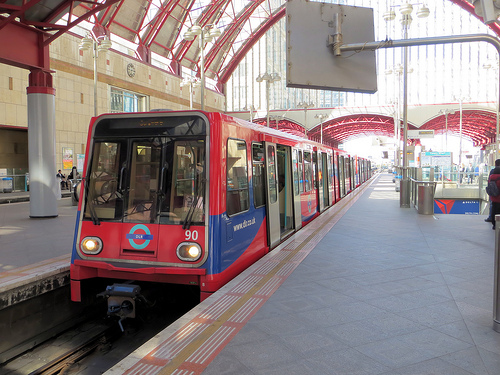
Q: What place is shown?
A: It is a train station.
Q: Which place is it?
A: It is a train station.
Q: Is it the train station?
A: Yes, it is the train station.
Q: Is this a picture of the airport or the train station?
A: It is showing the train station.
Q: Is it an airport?
A: No, it is a train station.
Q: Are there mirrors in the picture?
A: No, there are no mirrors.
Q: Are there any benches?
A: No, there are no benches.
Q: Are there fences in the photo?
A: No, there are no fences.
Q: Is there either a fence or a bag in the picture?
A: No, there are no fences or bags.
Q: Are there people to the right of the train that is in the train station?
A: Yes, there is a person to the right of the train.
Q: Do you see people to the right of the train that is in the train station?
A: Yes, there is a person to the right of the train.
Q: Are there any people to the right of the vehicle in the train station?
A: Yes, there is a person to the right of the train.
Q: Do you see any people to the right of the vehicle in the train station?
A: Yes, there is a person to the right of the train.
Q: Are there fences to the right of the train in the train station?
A: No, there is a person to the right of the train.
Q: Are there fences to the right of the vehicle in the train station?
A: No, there is a person to the right of the train.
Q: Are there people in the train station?
A: Yes, there is a person in the train station.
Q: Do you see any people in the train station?
A: Yes, there is a person in the train station.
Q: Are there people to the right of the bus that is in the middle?
A: Yes, there is a person to the right of the bus.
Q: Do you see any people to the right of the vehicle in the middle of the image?
A: Yes, there is a person to the right of the bus.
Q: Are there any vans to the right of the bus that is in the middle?
A: No, there is a person to the right of the bus.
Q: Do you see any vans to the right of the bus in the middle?
A: No, there is a person to the right of the bus.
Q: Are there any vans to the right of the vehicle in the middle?
A: No, there is a person to the right of the bus.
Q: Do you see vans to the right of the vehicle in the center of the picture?
A: No, there is a person to the right of the bus.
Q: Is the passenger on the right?
A: Yes, the passenger is on the right of the image.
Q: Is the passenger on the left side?
A: No, the passenger is on the right of the image.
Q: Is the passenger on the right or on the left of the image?
A: The passenger is on the right of the image.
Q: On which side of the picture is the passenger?
A: The passenger is on the right of the image.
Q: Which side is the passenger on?
A: The passenger is on the right of the image.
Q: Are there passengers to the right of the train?
A: Yes, there is a passenger to the right of the train.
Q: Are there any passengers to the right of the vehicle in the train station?
A: Yes, there is a passenger to the right of the train.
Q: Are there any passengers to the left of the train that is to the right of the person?
A: No, the passenger is to the right of the train.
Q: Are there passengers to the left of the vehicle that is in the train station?
A: No, the passenger is to the right of the train.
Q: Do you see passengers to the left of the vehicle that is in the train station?
A: No, the passenger is to the right of the train.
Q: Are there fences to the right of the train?
A: No, there is a passenger to the right of the train.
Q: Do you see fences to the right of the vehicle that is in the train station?
A: No, there is a passenger to the right of the train.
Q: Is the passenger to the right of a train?
A: Yes, the passenger is to the right of a train.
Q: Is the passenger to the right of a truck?
A: No, the passenger is to the right of a train.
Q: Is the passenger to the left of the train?
A: No, the passenger is to the right of the train.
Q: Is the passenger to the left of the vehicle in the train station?
A: No, the passenger is to the right of the train.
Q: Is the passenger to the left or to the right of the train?
A: The passenger is to the right of the train.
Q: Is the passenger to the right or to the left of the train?
A: The passenger is to the right of the train.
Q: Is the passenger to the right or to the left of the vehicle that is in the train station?
A: The passenger is to the right of the train.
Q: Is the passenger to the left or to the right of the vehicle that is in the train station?
A: The passenger is to the right of the train.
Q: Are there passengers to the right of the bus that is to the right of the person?
A: Yes, there is a passenger to the right of the bus.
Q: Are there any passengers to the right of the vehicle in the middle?
A: Yes, there is a passenger to the right of the bus.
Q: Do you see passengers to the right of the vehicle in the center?
A: Yes, there is a passenger to the right of the bus.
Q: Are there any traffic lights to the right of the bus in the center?
A: No, there is a passenger to the right of the bus.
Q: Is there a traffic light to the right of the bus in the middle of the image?
A: No, there is a passenger to the right of the bus.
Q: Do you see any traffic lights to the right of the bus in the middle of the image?
A: No, there is a passenger to the right of the bus.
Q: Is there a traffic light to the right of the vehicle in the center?
A: No, there is a passenger to the right of the bus.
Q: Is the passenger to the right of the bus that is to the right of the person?
A: Yes, the passenger is to the right of the bus.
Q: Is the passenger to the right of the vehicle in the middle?
A: Yes, the passenger is to the right of the bus.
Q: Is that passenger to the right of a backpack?
A: No, the passenger is to the right of the bus.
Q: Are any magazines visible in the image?
A: No, there are no magazines.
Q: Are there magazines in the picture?
A: No, there are no magazines.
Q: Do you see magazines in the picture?
A: No, there are no magazines.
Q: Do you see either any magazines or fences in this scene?
A: No, there are no magazines or fences.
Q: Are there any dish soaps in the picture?
A: No, there are no dish soaps.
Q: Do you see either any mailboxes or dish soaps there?
A: No, there are no dish soaps or mailboxes.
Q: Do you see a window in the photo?
A: Yes, there is a window.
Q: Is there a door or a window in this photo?
A: Yes, there is a window.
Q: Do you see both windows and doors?
A: Yes, there are both a window and doors.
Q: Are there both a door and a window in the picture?
A: Yes, there are both a window and a door.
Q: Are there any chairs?
A: No, there are no chairs.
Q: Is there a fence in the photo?
A: No, there are no fences.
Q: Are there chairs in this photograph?
A: No, there are no chairs.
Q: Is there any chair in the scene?
A: No, there are no chairs.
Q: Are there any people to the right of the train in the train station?
A: Yes, there is a person to the right of the train.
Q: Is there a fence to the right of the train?
A: No, there is a person to the right of the train.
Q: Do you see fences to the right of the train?
A: No, there is a person to the right of the train.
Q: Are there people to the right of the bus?
A: Yes, there is a person to the right of the bus.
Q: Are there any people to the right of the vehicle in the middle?
A: Yes, there is a person to the right of the bus.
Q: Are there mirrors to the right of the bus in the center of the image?
A: No, there is a person to the right of the bus.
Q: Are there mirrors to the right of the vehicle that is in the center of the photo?
A: No, there is a person to the right of the bus.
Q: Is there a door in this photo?
A: Yes, there is a door.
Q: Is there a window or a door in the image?
A: Yes, there is a door.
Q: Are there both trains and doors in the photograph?
A: Yes, there are both a door and a train.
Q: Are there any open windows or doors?
A: Yes, there is an open door.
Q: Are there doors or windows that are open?
A: Yes, the door is open.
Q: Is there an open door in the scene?
A: Yes, there is an open door.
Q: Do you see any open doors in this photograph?
A: Yes, there is an open door.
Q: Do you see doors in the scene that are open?
A: Yes, there is an open door.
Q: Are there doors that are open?
A: Yes, there is a door that is open.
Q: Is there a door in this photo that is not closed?
A: Yes, there is a open door.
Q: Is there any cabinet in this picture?
A: No, there are no cabinets.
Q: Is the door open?
A: Yes, the door is open.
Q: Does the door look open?
A: Yes, the door is open.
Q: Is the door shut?
A: No, the door is open.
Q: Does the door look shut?
A: No, the door is open.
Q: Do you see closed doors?
A: No, there is a door but it is open.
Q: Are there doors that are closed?
A: No, there is a door but it is open.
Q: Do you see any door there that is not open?
A: No, there is a door but it is open.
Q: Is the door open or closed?
A: The door is open.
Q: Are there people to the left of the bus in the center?
A: Yes, there is a person to the left of the bus.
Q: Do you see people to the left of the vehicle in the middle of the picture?
A: Yes, there is a person to the left of the bus.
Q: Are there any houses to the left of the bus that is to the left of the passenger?
A: No, there is a person to the left of the bus.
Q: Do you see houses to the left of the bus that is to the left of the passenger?
A: No, there is a person to the left of the bus.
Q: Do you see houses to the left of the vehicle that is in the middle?
A: No, there is a person to the left of the bus.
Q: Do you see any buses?
A: Yes, there is a bus.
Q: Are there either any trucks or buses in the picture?
A: Yes, there is a bus.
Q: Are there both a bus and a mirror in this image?
A: No, there is a bus but no mirrors.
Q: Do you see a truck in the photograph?
A: No, there are no trucks.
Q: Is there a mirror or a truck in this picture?
A: No, there are no trucks or mirrors.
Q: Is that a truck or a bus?
A: That is a bus.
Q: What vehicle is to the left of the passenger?
A: The vehicle is a bus.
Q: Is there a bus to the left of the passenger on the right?
A: Yes, there is a bus to the left of the passenger.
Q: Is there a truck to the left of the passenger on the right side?
A: No, there is a bus to the left of the passenger.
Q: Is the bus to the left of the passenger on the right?
A: Yes, the bus is to the left of the passenger.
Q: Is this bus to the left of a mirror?
A: No, the bus is to the left of the passenger.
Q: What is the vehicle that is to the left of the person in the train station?
A: The vehicle is a bus.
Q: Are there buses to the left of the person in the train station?
A: Yes, there is a bus to the left of the person.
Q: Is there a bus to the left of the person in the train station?
A: Yes, there is a bus to the left of the person.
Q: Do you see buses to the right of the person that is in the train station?
A: No, the bus is to the left of the person.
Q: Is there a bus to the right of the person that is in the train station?
A: No, the bus is to the left of the person.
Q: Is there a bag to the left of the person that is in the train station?
A: No, there is a bus to the left of the person.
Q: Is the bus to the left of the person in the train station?
A: Yes, the bus is to the left of the person.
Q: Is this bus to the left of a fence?
A: No, the bus is to the left of the person.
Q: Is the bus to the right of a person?
A: No, the bus is to the left of a person.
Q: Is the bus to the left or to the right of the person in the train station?
A: The bus is to the left of the person.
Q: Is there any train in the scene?
A: Yes, there is a train.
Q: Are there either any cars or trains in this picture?
A: Yes, there is a train.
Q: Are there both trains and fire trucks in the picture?
A: No, there is a train but no fire trucks.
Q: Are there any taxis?
A: No, there are no taxis.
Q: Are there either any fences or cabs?
A: No, there are no cabs or fences.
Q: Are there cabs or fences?
A: No, there are no cabs or fences.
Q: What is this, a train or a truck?
A: This is a train.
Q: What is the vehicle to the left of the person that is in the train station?
A: The vehicle is a train.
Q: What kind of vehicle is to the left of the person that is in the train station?
A: The vehicle is a train.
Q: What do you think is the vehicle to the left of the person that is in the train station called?
A: The vehicle is a train.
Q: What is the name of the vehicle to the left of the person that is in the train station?
A: The vehicle is a train.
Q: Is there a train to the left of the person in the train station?
A: Yes, there is a train to the left of the person.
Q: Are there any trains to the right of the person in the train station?
A: No, the train is to the left of the person.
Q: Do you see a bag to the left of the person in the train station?
A: No, there is a train to the left of the person.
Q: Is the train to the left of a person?
A: Yes, the train is to the left of a person.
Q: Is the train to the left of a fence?
A: No, the train is to the left of a person.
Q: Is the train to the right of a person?
A: No, the train is to the left of a person.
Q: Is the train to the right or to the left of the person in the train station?
A: The train is to the left of the person.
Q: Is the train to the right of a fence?
A: No, the train is to the right of a person.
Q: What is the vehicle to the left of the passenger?
A: The vehicle is a train.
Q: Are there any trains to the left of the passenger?
A: Yes, there is a train to the left of the passenger.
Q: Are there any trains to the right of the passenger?
A: No, the train is to the left of the passenger.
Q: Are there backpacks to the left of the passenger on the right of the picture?
A: No, there is a train to the left of the passenger.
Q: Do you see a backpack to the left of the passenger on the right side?
A: No, there is a train to the left of the passenger.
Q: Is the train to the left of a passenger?
A: Yes, the train is to the left of a passenger.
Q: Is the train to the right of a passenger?
A: No, the train is to the left of a passenger.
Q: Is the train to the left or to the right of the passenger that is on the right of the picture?
A: The train is to the left of the passenger.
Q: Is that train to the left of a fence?
A: No, the train is to the left of a person.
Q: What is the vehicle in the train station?
A: The vehicle is a train.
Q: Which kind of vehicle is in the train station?
A: The vehicle is a train.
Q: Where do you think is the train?
A: The train is in the train station.